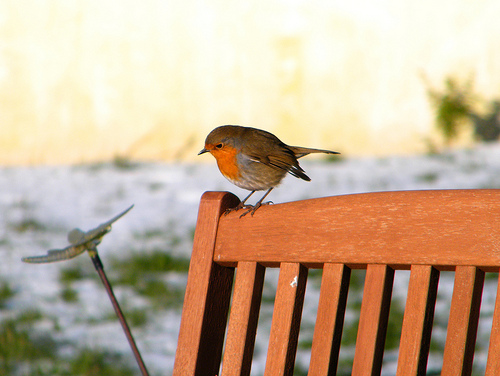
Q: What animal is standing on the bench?
A: A bird.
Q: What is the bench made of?
A: Wood.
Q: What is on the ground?
A: Snow.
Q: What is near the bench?
A: A solar light.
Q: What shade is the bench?
A: Brown.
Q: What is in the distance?
A: Grass.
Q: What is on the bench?
A: The birds feet.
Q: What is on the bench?
A: An orange and brown bird on a bench.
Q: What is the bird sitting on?
A: A brown wooden bench.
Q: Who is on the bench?
A: A bird on top of a bench.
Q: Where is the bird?
A: Perched on the bench.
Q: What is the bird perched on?
A: A bench.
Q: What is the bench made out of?
A: Wood material.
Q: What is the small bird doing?
A: Perching on the bench.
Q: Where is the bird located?
A: On a bench.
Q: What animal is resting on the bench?
A: A bird.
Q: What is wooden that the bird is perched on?
A: A bench.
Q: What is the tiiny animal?
A: A bird.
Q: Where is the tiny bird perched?
A: On a bench.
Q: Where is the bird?
A: On the bench.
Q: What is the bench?
A: Outside on the patio.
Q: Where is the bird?
A: On the bench.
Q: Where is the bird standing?
A: On the wood bench.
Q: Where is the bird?
A: On the bench.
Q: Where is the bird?
A: On the bench.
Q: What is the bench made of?
A: Wood.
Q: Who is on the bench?
A: A bird.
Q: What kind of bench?
A: A bench with slats.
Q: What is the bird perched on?
A: A bench.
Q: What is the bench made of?
A: Wood.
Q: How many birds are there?
A: 1.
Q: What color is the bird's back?
A: Brown.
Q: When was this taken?
A: Daytime.